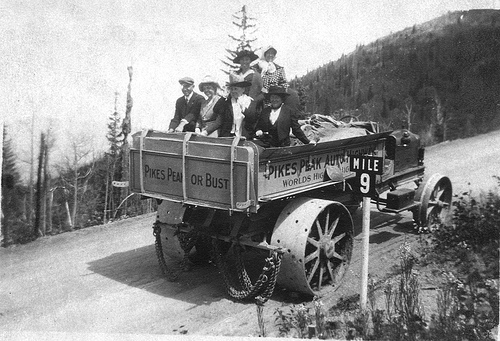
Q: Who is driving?
A: Man.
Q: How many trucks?
A: One.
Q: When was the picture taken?
A: Daytime.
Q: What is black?
A: Sign.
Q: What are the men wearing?
A: Hats.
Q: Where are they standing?
A: Truck.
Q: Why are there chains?
A: Going up mountain.